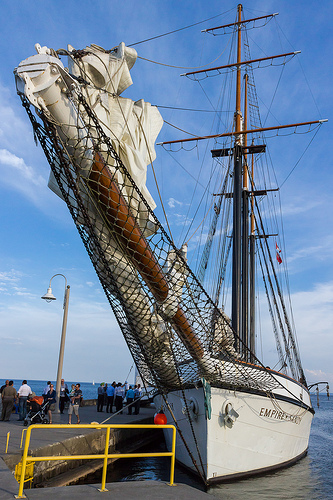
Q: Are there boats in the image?
A: Yes, there is a boat.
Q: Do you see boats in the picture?
A: Yes, there is a boat.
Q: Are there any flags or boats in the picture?
A: Yes, there is a boat.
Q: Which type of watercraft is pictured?
A: The watercraft is a boat.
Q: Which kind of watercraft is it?
A: The watercraft is a boat.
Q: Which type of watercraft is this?
A: This is a boat.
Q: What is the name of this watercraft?
A: This is a boat.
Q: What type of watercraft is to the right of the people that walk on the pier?
A: The watercraft is a boat.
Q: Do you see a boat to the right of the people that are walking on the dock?
A: Yes, there is a boat to the right of the people.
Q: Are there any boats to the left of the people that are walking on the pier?
A: No, the boat is to the right of the people.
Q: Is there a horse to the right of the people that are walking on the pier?
A: No, there is a boat to the right of the people.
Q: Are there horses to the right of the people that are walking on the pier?
A: No, there is a boat to the right of the people.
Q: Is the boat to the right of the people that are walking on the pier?
A: Yes, the boat is to the right of the people.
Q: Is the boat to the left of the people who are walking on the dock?
A: No, the boat is to the right of the people.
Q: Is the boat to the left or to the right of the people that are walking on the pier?
A: The boat is to the right of the people.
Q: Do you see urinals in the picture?
A: No, there are no urinals.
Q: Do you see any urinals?
A: No, there are no urinals.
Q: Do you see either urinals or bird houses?
A: No, there are no urinals or bird houses.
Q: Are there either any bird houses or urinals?
A: No, there are no urinals or bird houses.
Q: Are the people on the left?
A: Yes, the people are on the left of the image.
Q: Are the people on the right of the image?
A: No, the people are on the left of the image.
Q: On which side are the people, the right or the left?
A: The people are on the left of the image.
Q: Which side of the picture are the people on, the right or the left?
A: The people are on the left of the image.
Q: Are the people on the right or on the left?
A: The people are on the left of the image.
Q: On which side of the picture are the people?
A: The people are on the left of the image.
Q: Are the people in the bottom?
A: Yes, the people are in the bottom of the image.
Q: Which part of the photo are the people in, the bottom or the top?
A: The people are in the bottom of the image.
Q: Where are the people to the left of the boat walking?
A: The people are walking on the dock.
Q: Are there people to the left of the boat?
A: Yes, there are people to the left of the boat.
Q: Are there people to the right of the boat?
A: No, the people are to the left of the boat.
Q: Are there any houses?
A: No, there are no houses.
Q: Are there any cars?
A: No, there are no cars.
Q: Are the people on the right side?
A: No, the people are on the left of the image.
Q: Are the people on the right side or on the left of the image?
A: The people are on the left of the image.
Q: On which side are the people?
A: The people are on the left of the image.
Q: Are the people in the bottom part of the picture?
A: Yes, the people are in the bottom of the image.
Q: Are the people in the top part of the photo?
A: No, the people are in the bottom of the image.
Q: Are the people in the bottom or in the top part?
A: The people are in the bottom of the image.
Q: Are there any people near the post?
A: Yes, there are people near the post.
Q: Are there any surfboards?
A: No, there are no surfboards.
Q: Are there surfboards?
A: No, there are no surfboards.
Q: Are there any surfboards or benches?
A: No, there are no surfboards or benches.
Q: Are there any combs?
A: No, there are no combs.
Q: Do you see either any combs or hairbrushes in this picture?
A: No, there are no combs or hairbrushes.